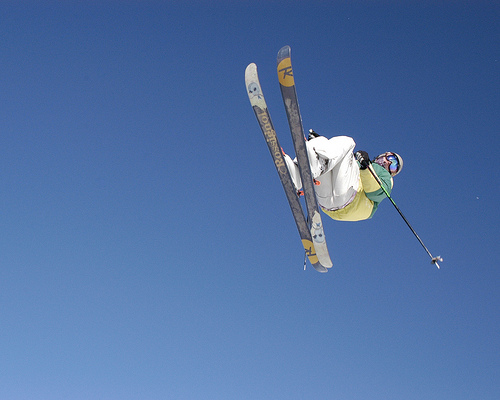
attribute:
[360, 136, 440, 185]
helmet — white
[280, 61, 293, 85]
letter — yellow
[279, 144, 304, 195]
boot — white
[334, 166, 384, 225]
jacket — green, yellow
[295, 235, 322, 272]
r — yellow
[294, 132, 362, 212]
pants — white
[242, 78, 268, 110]
alien — drawing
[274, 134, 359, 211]
ski pants — pair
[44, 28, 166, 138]
clouds — white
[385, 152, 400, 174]
goggles — pair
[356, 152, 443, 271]
ski pole — black and green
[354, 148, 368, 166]
glove — black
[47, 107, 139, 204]
sky — blue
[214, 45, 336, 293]
skis — pair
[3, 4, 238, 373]
sky — clear blue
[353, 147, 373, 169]
hand — gloved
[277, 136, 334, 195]
ski boot — white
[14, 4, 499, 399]
sky — blue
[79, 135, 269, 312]
sky — blue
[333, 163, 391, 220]
jacket — yellow and green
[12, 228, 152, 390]
cloud — WHITE